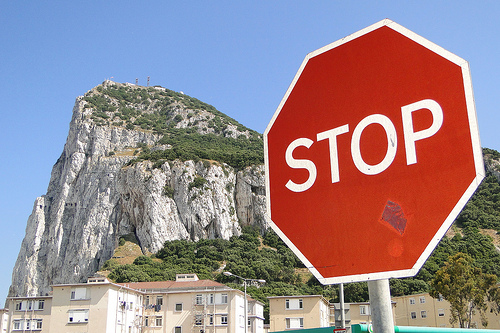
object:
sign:
[262, 19, 485, 286]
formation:
[62, 86, 240, 293]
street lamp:
[222, 271, 266, 333]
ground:
[435, 132, 472, 163]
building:
[0, 273, 265, 331]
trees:
[174, 114, 183, 122]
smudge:
[377, 198, 408, 257]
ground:
[378, 113, 419, 163]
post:
[263, 18, 487, 333]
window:
[221, 314, 227, 324]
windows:
[410, 311, 416, 319]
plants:
[230, 264, 257, 279]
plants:
[217, 274, 235, 283]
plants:
[273, 269, 306, 284]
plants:
[108, 264, 152, 283]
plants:
[155, 239, 196, 259]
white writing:
[285, 99, 443, 193]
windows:
[156, 316, 163, 326]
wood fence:
[248, 17, 483, 289]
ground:
[414, 152, 451, 184]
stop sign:
[262, 18, 488, 285]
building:
[264, 268, 499, 333]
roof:
[117, 279, 226, 289]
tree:
[428, 252, 498, 329]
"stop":
[284, 99, 444, 194]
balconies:
[14, 300, 45, 312]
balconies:
[193, 292, 229, 306]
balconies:
[192, 313, 229, 327]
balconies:
[13, 318, 43, 331]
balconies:
[144, 315, 164, 327]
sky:
[0, 2, 498, 308]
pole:
[366, 279, 395, 332]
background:
[0, 0, 499, 333]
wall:
[192, 227, 484, 317]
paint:
[377, 200, 407, 237]